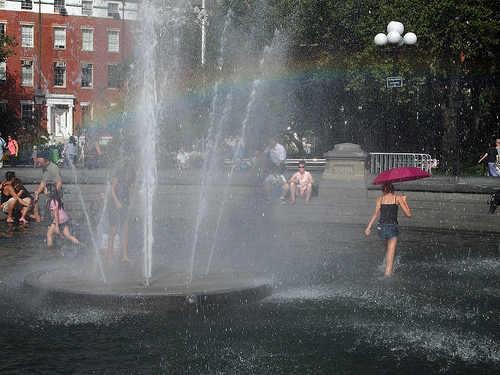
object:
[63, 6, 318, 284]
water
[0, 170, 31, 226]
people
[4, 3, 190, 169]
building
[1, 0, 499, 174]
background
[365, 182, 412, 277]
woman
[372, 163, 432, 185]
umbrella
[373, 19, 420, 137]
light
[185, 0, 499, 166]
trees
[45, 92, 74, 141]
entry way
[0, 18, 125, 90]
windows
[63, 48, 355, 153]
rainbow reflection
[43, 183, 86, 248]
girl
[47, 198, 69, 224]
pink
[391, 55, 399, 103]
pole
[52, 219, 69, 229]
shorts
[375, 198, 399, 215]
tank top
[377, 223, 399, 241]
shorts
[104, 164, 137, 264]
person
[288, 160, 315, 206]
person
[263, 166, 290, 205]
person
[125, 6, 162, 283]
stream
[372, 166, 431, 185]
fence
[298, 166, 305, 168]
sunglasses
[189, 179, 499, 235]
steps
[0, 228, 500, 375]
pool